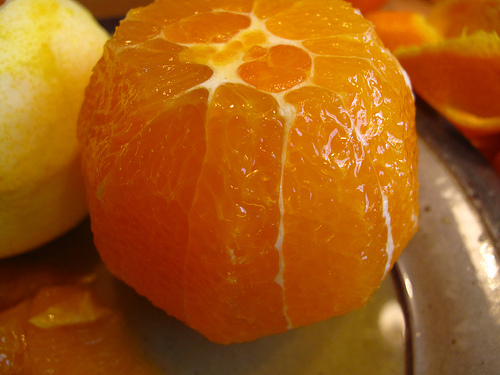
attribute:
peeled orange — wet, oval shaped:
[72, 1, 425, 349]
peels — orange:
[386, 2, 498, 154]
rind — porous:
[368, 12, 498, 140]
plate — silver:
[0, 99, 500, 370]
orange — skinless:
[81, 22, 421, 337]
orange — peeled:
[241, 85, 377, 238]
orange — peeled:
[70, 1, 455, 361]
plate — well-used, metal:
[9, 14, 494, 372]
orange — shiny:
[210, 139, 259, 234]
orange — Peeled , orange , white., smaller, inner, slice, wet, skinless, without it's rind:
[80, 2, 440, 337]